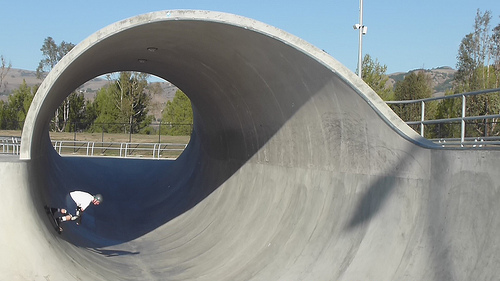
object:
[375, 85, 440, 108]
pole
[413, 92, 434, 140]
zebra stripes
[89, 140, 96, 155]
pole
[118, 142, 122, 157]
pole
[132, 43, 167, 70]
lights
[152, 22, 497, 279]
skate ramp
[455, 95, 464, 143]
fence pole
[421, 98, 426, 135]
fence pole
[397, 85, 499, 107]
fence pole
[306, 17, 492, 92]
tree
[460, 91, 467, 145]
pole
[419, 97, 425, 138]
pole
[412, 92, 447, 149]
pole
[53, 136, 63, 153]
pole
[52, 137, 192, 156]
fence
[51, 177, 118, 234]
skateboarder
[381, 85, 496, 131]
fence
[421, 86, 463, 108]
pole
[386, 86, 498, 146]
metal fence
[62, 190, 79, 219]
shorts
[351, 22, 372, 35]
lights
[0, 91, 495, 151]
fence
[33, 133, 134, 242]
person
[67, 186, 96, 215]
t-shirt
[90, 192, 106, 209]
head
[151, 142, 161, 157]
metal pole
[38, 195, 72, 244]
shoes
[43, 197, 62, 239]
soles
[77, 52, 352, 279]
cylinder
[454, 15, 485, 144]
tree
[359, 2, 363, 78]
pole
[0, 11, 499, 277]
ramp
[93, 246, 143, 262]
shadow